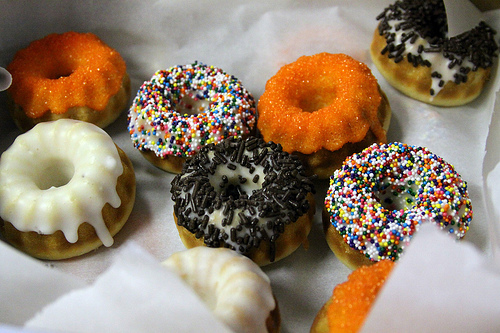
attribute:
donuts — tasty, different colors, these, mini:
[126, 43, 389, 262]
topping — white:
[0, 117, 127, 234]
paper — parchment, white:
[174, 11, 301, 58]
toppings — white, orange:
[265, 47, 378, 150]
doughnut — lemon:
[174, 243, 278, 328]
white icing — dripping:
[70, 196, 127, 253]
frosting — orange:
[274, 87, 291, 113]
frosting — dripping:
[95, 186, 126, 209]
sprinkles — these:
[160, 71, 220, 90]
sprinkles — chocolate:
[253, 142, 275, 162]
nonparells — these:
[123, 5, 143, 49]